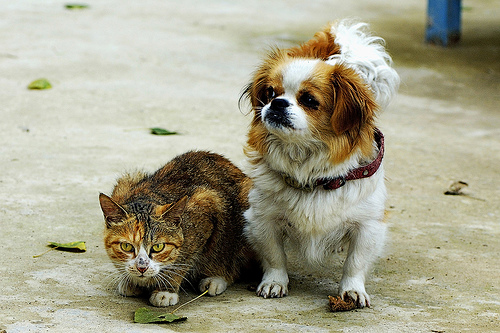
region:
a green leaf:
[26, 76, 51, 91]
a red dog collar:
[266, 126, 384, 191]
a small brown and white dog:
[238, 18, 400, 306]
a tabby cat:
[98, 150, 260, 305]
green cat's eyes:
[117, 238, 167, 255]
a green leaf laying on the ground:
[33, 231, 88, 260]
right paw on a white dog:
[254, 273, 289, 297]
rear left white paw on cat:
[201, 277, 228, 296]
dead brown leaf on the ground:
[445, 178, 469, 195]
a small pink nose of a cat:
[135, 261, 148, 273]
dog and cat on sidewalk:
[86, 41, 414, 295]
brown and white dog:
[241, 65, 397, 181]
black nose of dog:
[265, 98, 297, 127]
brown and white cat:
[98, 156, 228, 285]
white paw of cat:
[197, 268, 230, 308]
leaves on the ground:
[46, 53, 197, 157]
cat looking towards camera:
[93, 199, 185, 304]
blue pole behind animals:
[405, 3, 477, 53]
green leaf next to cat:
[142, 297, 194, 332]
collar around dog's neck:
[278, 109, 413, 223]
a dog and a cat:
[92, 17, 400, 310]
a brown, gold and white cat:
[88, 139, 269, 321]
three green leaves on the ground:
[7, 57, 180, 259]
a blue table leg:
[408, 0, 478, 65]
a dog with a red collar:
[228, 12, 398, 196]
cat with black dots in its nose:
[86, 190, 184, 285]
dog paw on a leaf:
[304, 234, 399, 320]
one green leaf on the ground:
[113, 273, 223, 323]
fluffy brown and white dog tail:
[276, 13, 413, 115]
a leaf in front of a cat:
[130, 289, 216, 324]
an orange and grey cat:
[97, 147, 252, 296]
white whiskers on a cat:
[91, 256, 196, 297]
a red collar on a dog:
[271, 121, 392, 187]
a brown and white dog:
[253, 19, 412, 319]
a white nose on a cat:
[125, 246, 158, 276]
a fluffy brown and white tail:
[303, 21, 428, 111]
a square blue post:
[418, 2, 471, 47]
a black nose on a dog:
[268, 98, 286, 114]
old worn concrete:
[1, 1, 495, 329]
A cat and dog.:
[45, 1, 435, 329]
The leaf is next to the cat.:
[131, 283, 221, 329]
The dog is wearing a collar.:
[243, 136, 401, 194]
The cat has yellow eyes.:
[100, 221, 176, 256]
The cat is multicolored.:
[80, 136, 255, 319]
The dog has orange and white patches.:
[210, 22, 415, 310]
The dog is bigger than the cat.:
[65, 12, 416, 324]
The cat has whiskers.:
[90, 246, 197, 298]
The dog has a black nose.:
[261, 93, 294, 114]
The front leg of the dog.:
[335, 218, 392, 332]